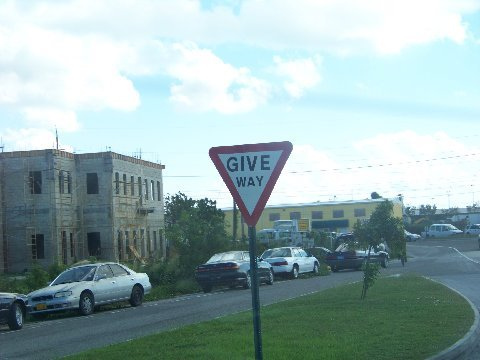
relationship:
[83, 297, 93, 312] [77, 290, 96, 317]
hubcap on tire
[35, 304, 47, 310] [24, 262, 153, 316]
license plate on car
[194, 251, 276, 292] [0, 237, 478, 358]
car parked on road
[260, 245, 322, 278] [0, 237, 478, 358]
car parked on road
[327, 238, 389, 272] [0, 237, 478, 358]
car parked on road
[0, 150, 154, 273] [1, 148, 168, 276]
scaffold on side of building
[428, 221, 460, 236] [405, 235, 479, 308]
van parked on road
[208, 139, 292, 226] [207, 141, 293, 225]
black sign on sign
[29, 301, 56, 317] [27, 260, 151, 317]
license plate on a blue parked car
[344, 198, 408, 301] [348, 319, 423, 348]
green tree in grass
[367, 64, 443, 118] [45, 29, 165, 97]
clouds in sky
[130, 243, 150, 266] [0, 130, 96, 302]
staircase side building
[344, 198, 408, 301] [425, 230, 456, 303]
green tree in road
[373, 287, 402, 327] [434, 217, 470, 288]
grass in road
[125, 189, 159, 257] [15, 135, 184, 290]
metal on building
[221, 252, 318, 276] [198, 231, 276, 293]
door on car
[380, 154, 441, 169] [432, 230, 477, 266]
wires on roadway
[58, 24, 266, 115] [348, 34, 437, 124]
white fluffy clouds in sky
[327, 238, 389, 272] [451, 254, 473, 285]
car on road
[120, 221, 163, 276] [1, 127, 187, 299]
staircase on building